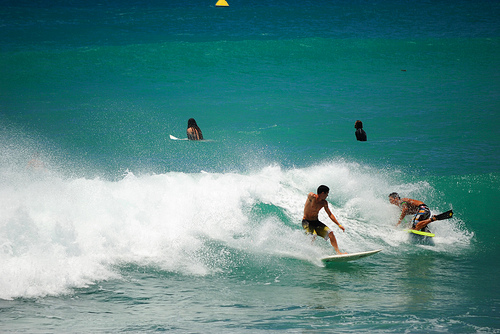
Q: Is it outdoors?
A: Yes, it is outdoors.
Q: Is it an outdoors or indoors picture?
A: It is outdoors.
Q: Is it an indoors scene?
A: No, it is outdoors.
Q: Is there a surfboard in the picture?
A: Yes, there is a surfboard.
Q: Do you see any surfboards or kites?
A: Yes, there is a surfboard.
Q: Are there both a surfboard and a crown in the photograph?
A: No, there is a surfboard but no crowns.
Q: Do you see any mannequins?
A: No, there are no mannequins.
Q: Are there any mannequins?
A: No, there are no mannequins.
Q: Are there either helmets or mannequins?
A: No, there are no mannequins or helmets.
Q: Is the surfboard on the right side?
A: Yes, the surfboard is on the right of the image.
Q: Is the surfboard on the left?
A: No, the surfboard is on the right of the image.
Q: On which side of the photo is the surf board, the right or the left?
A: The surf board is on the right of the image.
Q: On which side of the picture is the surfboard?
A: The surfboard is on the right of the image.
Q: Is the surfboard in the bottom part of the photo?
A: Yes, the surfboard is in the bottom of the image.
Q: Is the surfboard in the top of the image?
A: No, the surfboard is in the bottom of the image.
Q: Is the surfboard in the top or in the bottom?
A: The surfboard is in the bottom of the image.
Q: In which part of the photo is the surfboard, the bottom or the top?
A: The surfboard is in the bottom of the image.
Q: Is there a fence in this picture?
A: No, there are no fences.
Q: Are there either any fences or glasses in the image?
A: No, there are no fences or glasses.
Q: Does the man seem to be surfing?
A: Yes, the man is surfing.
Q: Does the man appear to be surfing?
A: Yes, the man is surfing.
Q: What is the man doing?
A: The man is surfing.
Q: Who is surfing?
A: The man is surfing.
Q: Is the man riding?
A: No, the man is surfing.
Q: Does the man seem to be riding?
A: No, the man is surfing.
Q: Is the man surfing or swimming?
A: The man is surfing.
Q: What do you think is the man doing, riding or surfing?
A: The man is surfing.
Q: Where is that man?
A: The man is in the water.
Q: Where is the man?
A: The man is in the water.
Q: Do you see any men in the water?
A: Yes, there is a man in the water.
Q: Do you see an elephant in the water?
A: No, there is a man in the water.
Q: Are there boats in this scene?
A: No, there are no boats.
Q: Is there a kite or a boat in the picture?
A: No, there are no boats or kites.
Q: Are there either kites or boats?
A: No, there are no boats or kites.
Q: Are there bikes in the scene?
A: No, there are no bikes.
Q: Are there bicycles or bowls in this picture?
A: No, there are no bicycles or bowls.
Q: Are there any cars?
A: No, there are no cars.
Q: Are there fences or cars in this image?
A: No, there are no cars or fences.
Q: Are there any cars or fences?
A: No, there are no cars or fences.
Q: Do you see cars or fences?
A: No, there are no cars or fences.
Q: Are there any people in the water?
A: Yes, there is a person in the water.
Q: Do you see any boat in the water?
A: No, there is a person in the water.